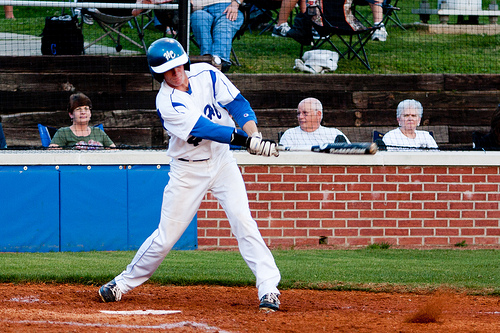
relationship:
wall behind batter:
[197, 164, 497, 251] [120, 38, 315, 300]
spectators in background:
[277, 97, 441, 151] [2, 0, 498, 146]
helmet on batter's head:
[139, 33, 184, 80] [148, 34, 188, 78]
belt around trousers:
[171, 149, 212, 163] [116, 157, 281, 299]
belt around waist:
[171, 149, 212, 163] [162, 145, 234, 167]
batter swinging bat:
[97, 37, 286, 313] [277, 140, 379, 157]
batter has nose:
[84, 17, 297, 314] [165, 60, 183, 75]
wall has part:
[198, 164, 498, 251] [401, 213, 417, 231]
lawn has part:
[264, 234, 482, 279] [401, 264, 421, 273]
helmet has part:
[146, 37, 190, 84] [168, 47, 180, 56]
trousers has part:
[114, 150, 282, 300] [164, 224, 174, 240]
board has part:
[57, 164, 132, 252] [97, 214, 109, 228]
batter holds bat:
[97, 37, 286, 313] [265, 135, 380, 167]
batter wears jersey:
[97, 37, 286, 313] [150, 65, 262, 154]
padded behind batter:
[1, 161, 193, 254] [97, 33, 283, 313]